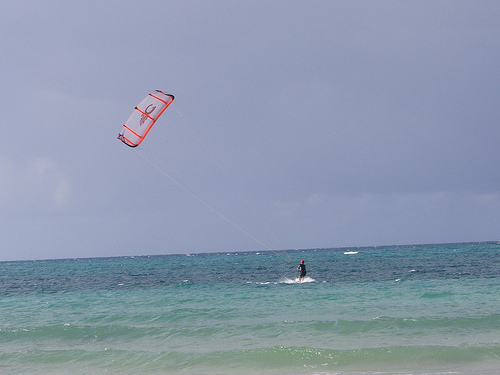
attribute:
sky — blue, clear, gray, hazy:
[12, 17, 488, 207]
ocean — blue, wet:
[16, 260, 486, 374]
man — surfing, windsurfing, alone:
[292, 257, 310, 284]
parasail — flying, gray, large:
[117, 83, 175, 151]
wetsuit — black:
[302, 267, 306, 277]